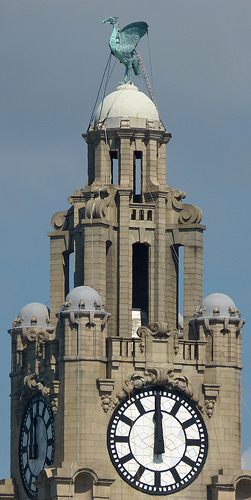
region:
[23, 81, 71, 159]
Bright blue sky far above.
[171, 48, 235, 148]
No clouds in the sky today.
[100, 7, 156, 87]
Green bird on top of the tower.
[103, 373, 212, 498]
Large clock in the tower.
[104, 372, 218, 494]
Large clock with a white face.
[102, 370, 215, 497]
Round clock with black marks.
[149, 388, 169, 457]
Black hands on the clock.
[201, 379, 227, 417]
Small shelf on the tower.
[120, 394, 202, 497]
this is a clock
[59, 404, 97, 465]
this is a wall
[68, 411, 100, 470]
the wall is grey in colour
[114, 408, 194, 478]
the clock is black and white in colour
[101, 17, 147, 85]
this is a flamingo monument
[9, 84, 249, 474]
this is a building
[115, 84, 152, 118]
this is the roof top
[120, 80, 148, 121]
the roof top is white in colour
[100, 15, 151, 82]
the monument is blue in colour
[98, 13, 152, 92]
blue animal on top of dome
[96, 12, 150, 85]
blue animal sculpture on top of dome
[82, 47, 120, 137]
safety straps securing sculpture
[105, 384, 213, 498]
black and white clock face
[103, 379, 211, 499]
clock that reads twelve o'clock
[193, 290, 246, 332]
small gray dome on tower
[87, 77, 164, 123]
large white dome on tower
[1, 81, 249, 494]
stone clock tower with dome on top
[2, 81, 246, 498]
clock tower with sculpture on top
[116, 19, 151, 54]
blue wing on sculpture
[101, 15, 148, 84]
green bronze statue of a bird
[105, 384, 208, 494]
clock face reading 12:00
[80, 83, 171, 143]
white dome atop a tower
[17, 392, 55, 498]
clock face reading 12:00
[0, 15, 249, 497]
large monumental clock tower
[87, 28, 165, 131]
cables attached to a piece of statuary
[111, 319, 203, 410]
curly details of a stone tower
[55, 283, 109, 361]
grey domed detail of a tower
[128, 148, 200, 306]
cable attached to two parts of a tower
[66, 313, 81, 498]
dripping grey stains on a tower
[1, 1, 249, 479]
blue of daytime sky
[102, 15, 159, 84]
side of bird sculpture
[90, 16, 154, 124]
cables on bird sculpture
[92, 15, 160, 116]
white dome under bird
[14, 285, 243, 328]
three gray domes on tower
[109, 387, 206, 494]
clock with white face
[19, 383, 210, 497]
two clocks on two sides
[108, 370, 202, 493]
design element above clock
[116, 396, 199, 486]
black lines in place of numbers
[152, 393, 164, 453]
two clock hands pointing up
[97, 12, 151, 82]
a large statue on a bird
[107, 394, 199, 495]
a clock that is big and white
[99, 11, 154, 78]
a statue of a blue bird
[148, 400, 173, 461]
the hands on a big clock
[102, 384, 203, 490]
a very round white clock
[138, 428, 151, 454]
the cracks on a big clock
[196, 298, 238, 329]
a dome that is on a roof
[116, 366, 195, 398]
the design on a clock building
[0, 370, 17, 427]
a sky that is really blue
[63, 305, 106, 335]
some designs on a dome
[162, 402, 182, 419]
a black bar that represents a number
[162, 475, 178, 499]
white dots that represent seconds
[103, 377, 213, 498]
a black and white clock